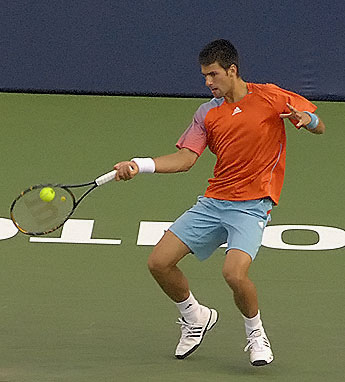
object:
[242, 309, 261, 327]
sock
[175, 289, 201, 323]
sock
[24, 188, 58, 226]
strings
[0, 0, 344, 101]
blue wall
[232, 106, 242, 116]
logo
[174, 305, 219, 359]
shoes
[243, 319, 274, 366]
shoes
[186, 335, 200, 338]
lines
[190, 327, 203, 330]
lines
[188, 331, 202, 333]
lines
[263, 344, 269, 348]
lines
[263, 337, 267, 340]
lines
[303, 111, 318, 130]
sweatband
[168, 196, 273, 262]
shorts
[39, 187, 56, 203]
ball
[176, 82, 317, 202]
orange shirt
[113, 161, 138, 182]
hand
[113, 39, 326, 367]
man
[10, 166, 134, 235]
racket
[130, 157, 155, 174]
band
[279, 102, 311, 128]
hand